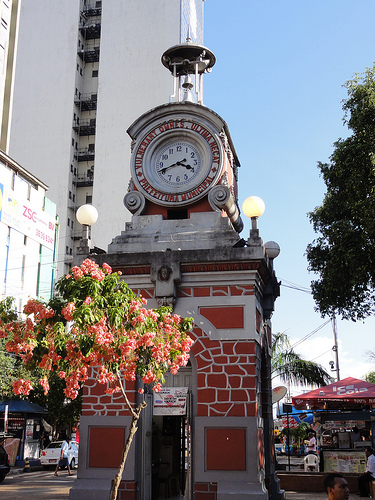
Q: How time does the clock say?
A: 3:42.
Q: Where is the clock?
A: On the top of the tower.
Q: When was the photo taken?
A: Daytime.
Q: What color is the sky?
A: Blue.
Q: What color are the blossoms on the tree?
A: Pink.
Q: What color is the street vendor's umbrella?
A: Red.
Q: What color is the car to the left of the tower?
A: White.